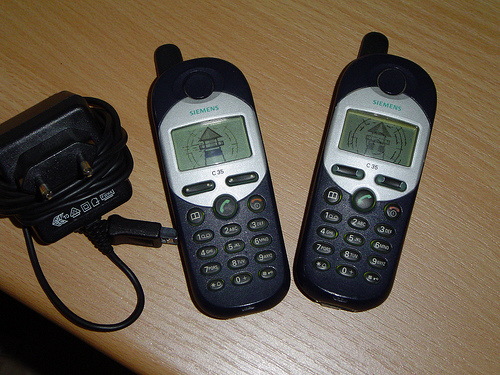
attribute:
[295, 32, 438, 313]
phone — black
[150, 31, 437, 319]
two phones — black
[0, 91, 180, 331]
charger — black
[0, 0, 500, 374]
table — brown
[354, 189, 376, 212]
button — green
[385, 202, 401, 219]
button — red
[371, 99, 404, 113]
letters — green